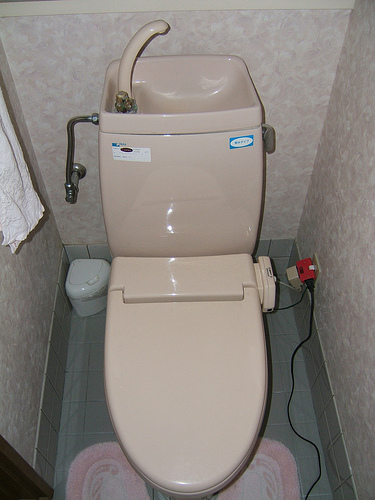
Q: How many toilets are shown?
A: One.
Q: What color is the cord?
A: Black.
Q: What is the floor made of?
A: Tile.